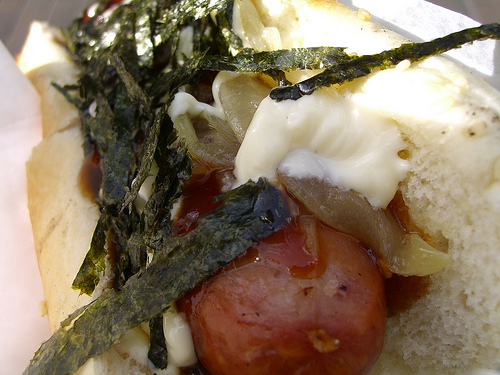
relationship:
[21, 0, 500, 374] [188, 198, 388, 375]
topping on hotdog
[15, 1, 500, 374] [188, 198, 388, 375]
bun under hotdog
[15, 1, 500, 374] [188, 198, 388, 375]
bun for hotdog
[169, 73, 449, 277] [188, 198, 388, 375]
onions on hotdog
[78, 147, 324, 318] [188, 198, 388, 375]
sauce on hotdog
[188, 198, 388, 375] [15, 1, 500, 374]
hotdog on bun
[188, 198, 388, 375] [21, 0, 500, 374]
hotdog with topping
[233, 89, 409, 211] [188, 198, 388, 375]
mayo on hotdog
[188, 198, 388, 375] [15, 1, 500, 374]
hotdog in bun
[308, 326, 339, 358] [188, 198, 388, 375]
tip of hotdog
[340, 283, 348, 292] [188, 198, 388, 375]
speck on hotdog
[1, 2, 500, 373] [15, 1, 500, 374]
wrapper around bun